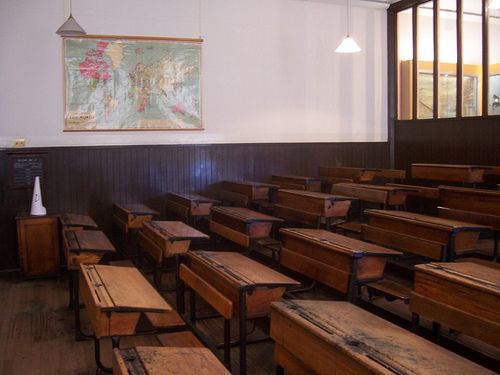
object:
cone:
[27, 174, 48, 216]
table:
[17, 214, 57, 281]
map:
[62, 33, 205, 132]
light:
[333, 0, 365, 56]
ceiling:
[311, 0, 396, 13]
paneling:
[3, 143, 393, 268]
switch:
[11, 137, 26, 149]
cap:
[26, 174, 48, 217]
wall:
[2, 0, 391, 148]